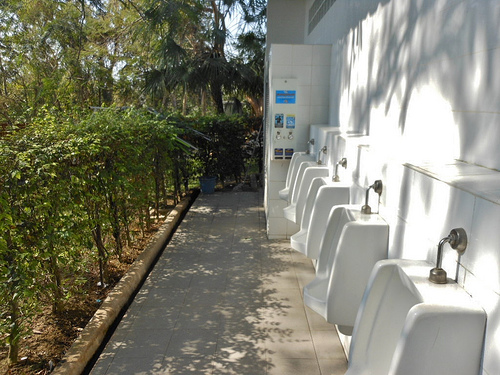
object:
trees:
[4, 7, 260, 136]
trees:
[1, 101, 184, 365]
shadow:
[79, 188, 293, 373]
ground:
[0, 182, 357, 374]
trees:
[173, 108, 265, 190]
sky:
[1, 2, 263, 84]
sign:
[276, 90, 297, 104]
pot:
[199, 176, 217, 194]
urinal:
[303, 204, 389, 327]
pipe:
[365, 185, 372, 205]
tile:
[309, 85, 329, 106]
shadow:
[321, 0, 499, 264]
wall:
[328, 2, 499, 373]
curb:
[59, 187, 198, 375]